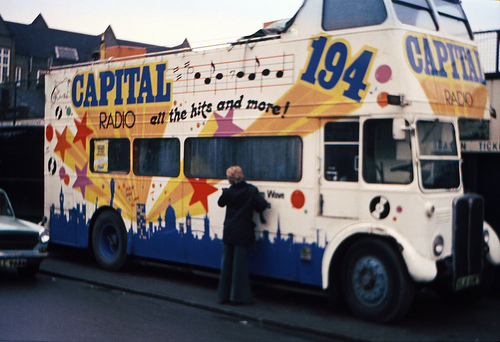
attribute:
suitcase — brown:
[98, 39, 148, 64]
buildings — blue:
[43, 177, 328, 289]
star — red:
[181, 173, 216, 215]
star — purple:
[71, 162, 94, 194]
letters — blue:
[69, 68, 169, 107]